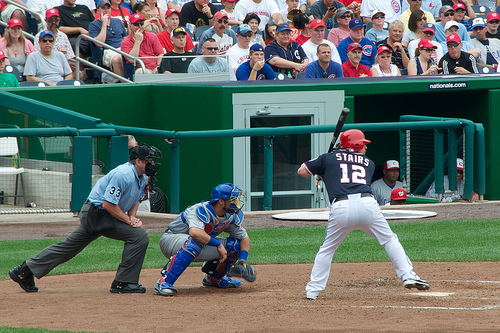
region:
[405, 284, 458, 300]
The white home plate.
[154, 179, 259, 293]
The umpire.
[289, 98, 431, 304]
A baseball player.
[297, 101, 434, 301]
A man holding a baseball bat, getting ready to swing.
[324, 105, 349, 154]
A black baseball bat.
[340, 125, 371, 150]
A red helmet.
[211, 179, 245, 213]
A blue helmet with a face protector.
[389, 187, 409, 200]
A red hat with a white design.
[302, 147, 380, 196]
A blue and white jersey with white lettering on the back.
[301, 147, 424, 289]
A baseball uniform.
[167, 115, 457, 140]
green railing on field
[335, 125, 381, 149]
red helmet protecting man's head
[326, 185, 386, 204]
white loops in white pants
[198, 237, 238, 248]
blue wrist band on man's wrist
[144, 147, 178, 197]
black face mask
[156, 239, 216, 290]
blue knee pad on the catcher's knee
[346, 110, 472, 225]
people sitting in the dugout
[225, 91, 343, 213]
door frame in the dug out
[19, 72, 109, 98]
empty seats in the stant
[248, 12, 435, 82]
people watching the game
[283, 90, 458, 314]
a batter about to hit a ball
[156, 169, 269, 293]
the catcher on a baseball team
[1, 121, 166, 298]
the umpire at a baseball game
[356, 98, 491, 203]
the dug out at a baseball game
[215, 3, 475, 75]
several people watching a baseball game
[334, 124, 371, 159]
a red baseball helmet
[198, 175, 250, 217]
a blue catcher's helmet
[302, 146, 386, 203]
a jersey with the number twelve on it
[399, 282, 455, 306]
home plate on a baseball field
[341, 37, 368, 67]
a man wearing a red baseball cap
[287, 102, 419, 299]
a man holding a bat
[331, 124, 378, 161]
a ma wearing a red helmet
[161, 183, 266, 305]
a man wearing a catchers uniform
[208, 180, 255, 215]
a man wearing a blue helmet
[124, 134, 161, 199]
a man wearing a black safety maks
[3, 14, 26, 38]
a woman wearing a red hat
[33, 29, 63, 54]
a man wearing sunglasses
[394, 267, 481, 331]
home plate on a baseball field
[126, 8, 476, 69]
several people sitting in the bleachers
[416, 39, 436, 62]
a woman wearing sunglasses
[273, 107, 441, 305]
the batter at the plate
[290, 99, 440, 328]
the batter on the field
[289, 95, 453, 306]
the batter holding the bat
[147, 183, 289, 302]
the catcher behind the batter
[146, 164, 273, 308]
the catcher is crouching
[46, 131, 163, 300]
the umpire behind the catcher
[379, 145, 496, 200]
the players in the dug out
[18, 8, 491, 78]
the spectators in the stands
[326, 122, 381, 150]
the red helmet on the head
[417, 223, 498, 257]
the grass is green and trimmed